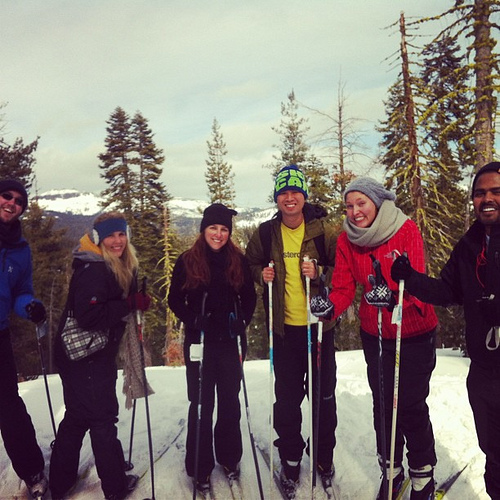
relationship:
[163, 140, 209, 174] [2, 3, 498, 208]
cloud in sky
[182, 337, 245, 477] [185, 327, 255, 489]
woman wearing pants